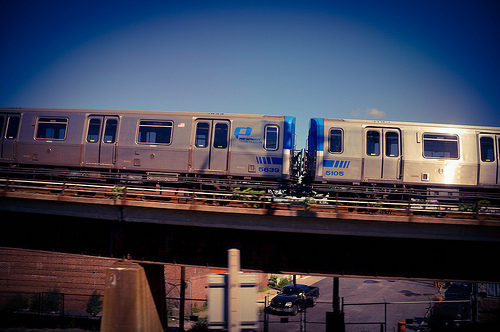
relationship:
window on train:
[384, 130, 399, 159] [0, 104, 500, 214]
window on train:
[366, 130, 380, 156] [0, 104, 500, 214]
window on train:
[330, 127, 342, 152] [0, 104, 500, 214]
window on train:
[265, 122, 278, 150] [0, 104, 500, 214]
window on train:
[135, 117, 173, 145] [0, 104, 500, 214]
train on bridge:
[6, 92, 494, 212] [0, 190, 500, 287]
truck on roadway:
[261, 281, 418, 331] [273, 275, 457, 329]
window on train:
[327, 127, 344, 154] [102, 90, 472, 244]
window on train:
[135, 117, 173, 144] [7, 100, 497, 193]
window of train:
[420, 128, 467, 160] [6, 92, 494, 212]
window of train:
[477, 128, 498, 163] [7, 100, 497, 193]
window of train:
[419, 131, 462, 161] [3, 96, 498, 228]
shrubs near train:
[231, 186, 266, 208] [6, 92, 494, 212]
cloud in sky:
[146, 24, 268, 85] [2, 0, 496, 142]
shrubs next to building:
[293, 151, 312, 188] [130, 248, 229, 305]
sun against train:
[374, 126, 478, 194] [6, 92, 494, 212]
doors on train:
[71, 107, 228, 171] [75, 57, 499, 270]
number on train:
[317, 166, 338, 183] [311, 121, 478, 227]